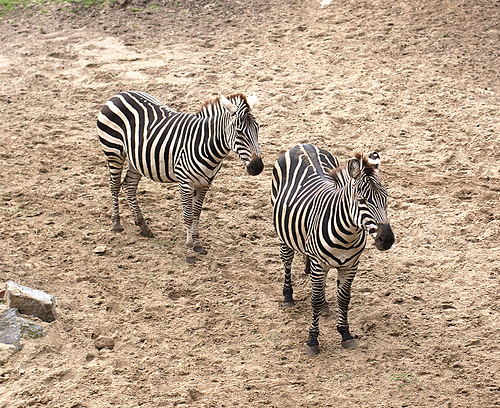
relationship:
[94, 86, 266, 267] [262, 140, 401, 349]
zebra behind or zebra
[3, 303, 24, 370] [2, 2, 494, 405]
rock on ground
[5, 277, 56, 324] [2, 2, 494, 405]
rock on ground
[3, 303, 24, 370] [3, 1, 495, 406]
rock in zebra habitat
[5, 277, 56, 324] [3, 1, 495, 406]
rock in zebra habitat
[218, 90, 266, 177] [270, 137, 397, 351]
head of zebra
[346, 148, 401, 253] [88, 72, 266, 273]
head of zebra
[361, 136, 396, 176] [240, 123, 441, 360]
ear on zebra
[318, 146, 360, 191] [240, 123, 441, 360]
ear on zebra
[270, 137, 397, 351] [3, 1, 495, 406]
zebra on zebra habitat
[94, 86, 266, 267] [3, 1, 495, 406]
zebra on zebra habitat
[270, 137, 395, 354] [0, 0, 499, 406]
zebra are on dirt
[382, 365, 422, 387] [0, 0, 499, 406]
grass on dirt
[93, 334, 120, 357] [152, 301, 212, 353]
rock on dirt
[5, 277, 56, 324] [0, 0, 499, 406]
rock on dirt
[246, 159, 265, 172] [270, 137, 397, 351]
nose on zebra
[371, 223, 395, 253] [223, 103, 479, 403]
nose of zebra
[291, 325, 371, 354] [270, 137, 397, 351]
feet of zebra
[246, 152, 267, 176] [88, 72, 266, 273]
nose of zebra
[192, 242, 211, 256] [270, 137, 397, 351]
foot of zebra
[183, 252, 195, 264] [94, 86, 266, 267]
foot of zebra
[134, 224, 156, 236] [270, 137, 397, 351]
foot of zebra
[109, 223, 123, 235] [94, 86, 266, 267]
foot of zebra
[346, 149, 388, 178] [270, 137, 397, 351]
ears of zebra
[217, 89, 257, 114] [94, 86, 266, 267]
ears of zebra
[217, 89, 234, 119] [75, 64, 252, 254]
ear of zebra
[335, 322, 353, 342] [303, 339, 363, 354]
area above hooves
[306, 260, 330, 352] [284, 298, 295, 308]
leg above hooves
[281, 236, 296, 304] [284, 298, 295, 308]
leg above hooves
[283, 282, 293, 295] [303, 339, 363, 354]
area above hooves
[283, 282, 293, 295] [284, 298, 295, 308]
area above hooves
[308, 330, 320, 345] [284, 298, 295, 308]
area above hooves